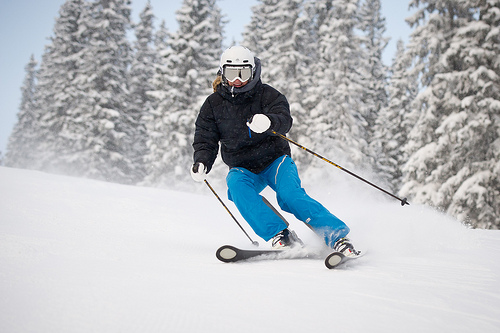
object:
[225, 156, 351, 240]
pants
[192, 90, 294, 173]
jacket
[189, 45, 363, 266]
woman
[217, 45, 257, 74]
helmet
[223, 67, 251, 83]
goggles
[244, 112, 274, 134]
gloves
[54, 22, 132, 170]
trees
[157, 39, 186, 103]
snow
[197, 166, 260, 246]
poles